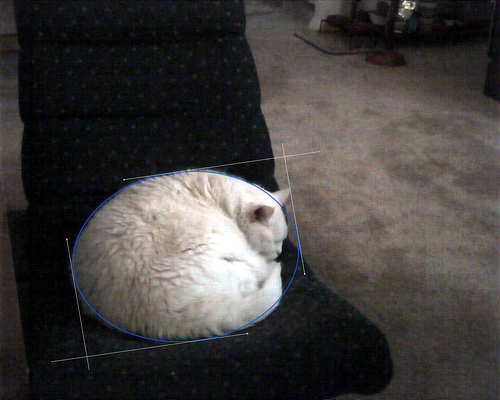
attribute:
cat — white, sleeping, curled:
[71, 169, 290, 339]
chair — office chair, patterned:
[7, 0, 391, 398]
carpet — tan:
[287, 31, 498, 388]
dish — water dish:
[367, 52, 410, 66]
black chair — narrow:
[11, 5, 413, 378]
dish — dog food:
[364, 44, 417, 74]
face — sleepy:
[263, 219, 295, 261]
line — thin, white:
[64, 239, 92, 371]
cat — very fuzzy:
[67, 164, 302, 349]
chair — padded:
[6, 41, 378, 393]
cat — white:
[35, 140, 318, 350]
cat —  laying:
[83, 161, 343, 344]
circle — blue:
[72, 169, 301, 341]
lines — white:
[49, 142, 320, 368]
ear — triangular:
[243, 200, 280, 224]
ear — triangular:
[269, 184, 290, 206]